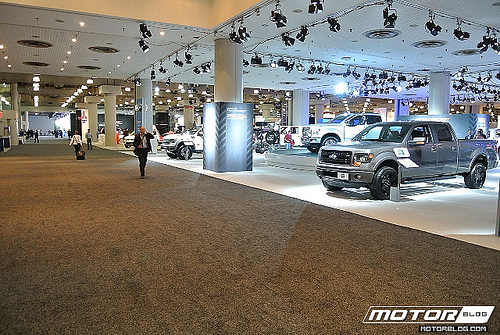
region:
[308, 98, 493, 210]
the car is gray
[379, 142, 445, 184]
white label on truck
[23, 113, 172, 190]
people are walking on carpet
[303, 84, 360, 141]
the truck is white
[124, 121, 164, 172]
man wearing a suit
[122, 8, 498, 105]
lights shining above cars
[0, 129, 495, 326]
the carpet is brown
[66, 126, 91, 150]
person's shirt is white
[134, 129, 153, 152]
man's shirt is white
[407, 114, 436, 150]
truck window is down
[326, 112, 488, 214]
shiny new truck on show room floor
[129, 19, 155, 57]
silver lights in white ceiling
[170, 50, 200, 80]
silver lights in white ceiling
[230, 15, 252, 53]
silver lights in white ceiling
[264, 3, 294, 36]
silver lights in white ceiling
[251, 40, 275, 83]
silver lights in white ceiling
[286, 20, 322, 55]
silver lights in white ceiling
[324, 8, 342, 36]
silver lights in white ceiling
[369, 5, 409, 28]
silver lights in white ceiling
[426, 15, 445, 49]
silver lights in white ceiling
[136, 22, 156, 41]
On pair of ceiling lights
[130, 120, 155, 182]
Man in dark jacket walking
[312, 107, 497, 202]
New gray pick-up truck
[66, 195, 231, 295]
Brown carpet inside convention center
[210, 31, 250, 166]
Supporting post in convention center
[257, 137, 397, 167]
Pedestal for white pick-up truck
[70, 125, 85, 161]
Woman walk and pulling luggage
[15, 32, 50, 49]
Air vent in ceiling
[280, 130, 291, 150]
Person in red shirt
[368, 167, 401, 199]
Black truck wheel with black rim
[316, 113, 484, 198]
new tuck in show room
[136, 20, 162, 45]
silver light in show room ceiling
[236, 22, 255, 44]
silver light in show room ceiling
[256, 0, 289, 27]
silver light in show room ceiling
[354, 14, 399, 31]
silver light in show room ceiling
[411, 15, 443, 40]
silver light in show room ceiling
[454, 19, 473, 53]
silver light in show room ceiling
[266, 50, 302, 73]
silver light in show room ceiling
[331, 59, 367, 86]
silver light in show room ceiling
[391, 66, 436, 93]
silver light in show room ceiling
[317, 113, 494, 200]
Large gray Ford truck is parked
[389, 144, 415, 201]
Information display next to truck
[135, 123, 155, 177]
Man walking on brown carpet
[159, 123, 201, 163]
White truck behind man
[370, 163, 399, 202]
Large round black rubber tire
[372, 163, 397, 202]
Large round black rubber tire on truck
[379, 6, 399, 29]
Black light above truck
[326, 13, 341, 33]
Black light above truck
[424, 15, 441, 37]
Black light above truck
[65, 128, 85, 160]
Woman in white shirt rolling suitcase